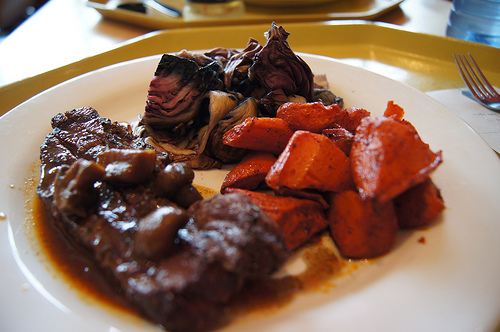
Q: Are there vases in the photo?
A: No, there are no vases.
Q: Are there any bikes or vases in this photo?
A: No, there are no vases or bikes.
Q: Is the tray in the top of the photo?
A: Yes, the tray is in the top of the image.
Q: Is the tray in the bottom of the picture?
A: No, the tray is in the top of the image.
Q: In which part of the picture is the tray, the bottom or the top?
A: The tray is in the top of the image.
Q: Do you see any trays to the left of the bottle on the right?
A: Yes, there is a tray to the left of the bottle.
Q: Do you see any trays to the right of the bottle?
A: No, the tray is to the left of the bottle.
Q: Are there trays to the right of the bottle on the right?
A: No, the tray is to the left of the bottle.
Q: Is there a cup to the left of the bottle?
A: No, there is a tray to the left of the bottle.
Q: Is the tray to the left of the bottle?
A: Yes, the tray is to the left of the bottle.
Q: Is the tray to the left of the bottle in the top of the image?
A: Yes, the tray is to the left of the bottle.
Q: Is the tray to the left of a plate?
A: No, the tray is to the left of the bottle.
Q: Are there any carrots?
A: Yes, there is a carrot.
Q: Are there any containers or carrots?
A: Yes, there is a carrot.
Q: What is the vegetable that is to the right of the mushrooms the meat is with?
A: The vegetable is a carrot.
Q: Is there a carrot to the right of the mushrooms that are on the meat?
A: Yes, there is a carrot to the right of the mushrooms.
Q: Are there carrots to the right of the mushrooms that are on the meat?
A: Yes, there is a carrot to the right of the mushrooms.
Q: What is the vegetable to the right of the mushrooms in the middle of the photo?
A: The vegetable is a carrot.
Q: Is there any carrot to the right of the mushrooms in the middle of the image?
A: Yes, there is a carrot to the right of the mushrooms.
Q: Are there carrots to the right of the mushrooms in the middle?
A: Yes, there is a carrot to the right of the mushrooms.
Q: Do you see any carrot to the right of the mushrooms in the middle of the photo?
A: Yes, there is a carrot to the right of the mushrooms.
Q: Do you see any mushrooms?
A: Yes, there are mushrooms.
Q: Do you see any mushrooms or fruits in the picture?
A: Yes, there are mushrooms.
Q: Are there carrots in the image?
A: Yes, there are carrots.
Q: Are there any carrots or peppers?
A: Yes, there are carrots.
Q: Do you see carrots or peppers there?
A: Yes, there are carrots.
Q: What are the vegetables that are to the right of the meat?
A: The vegetables are carrots.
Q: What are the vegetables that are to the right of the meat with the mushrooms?
A: The vegetables are carrots.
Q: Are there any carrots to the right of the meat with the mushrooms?
A: Yes, there are carrots to the right of the meat.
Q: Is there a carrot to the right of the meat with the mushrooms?
A: Yes, there are carrots to the right of the meat.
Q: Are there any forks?
A: Yes, there is a fork.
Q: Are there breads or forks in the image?
A: Yes, there is a fork.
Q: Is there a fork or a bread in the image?
A: Yes, there is a fork.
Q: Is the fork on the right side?
A: Yes, the fork is on the right of the image.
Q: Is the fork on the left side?
A: No, the fork is on the right of the image.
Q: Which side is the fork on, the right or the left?
A: The fork is on the right of the image.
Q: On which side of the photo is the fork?
A: The fork is on the right of the image.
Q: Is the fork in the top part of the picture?
A: Yes, the fork is in the top of the image.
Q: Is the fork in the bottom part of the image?
A: No, the fork is in the top of the image.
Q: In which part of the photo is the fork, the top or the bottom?
A: The fork is in the top of the image.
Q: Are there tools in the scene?
A: No, there are no tools.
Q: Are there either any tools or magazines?
A: No, there are no tools or magazines.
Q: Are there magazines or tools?
A: No, there are no tools or magazines.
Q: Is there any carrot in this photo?
A: Yes, there is a carrot.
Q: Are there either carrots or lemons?
A: Yes, there is a carrot.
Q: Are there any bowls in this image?
A: No, there are no bowls.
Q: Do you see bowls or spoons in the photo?
A: No, there are no bowls or spoons.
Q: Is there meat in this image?
A: Yes, there is meat.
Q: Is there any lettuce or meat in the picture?
A: Yes, there is meat.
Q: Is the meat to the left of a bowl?
A: No, the meat is to the left of a carrot.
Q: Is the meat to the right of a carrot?
A: No, the meat is to the left of a carrot.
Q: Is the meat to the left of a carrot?
A: Yes, the meat is to the left of a carrot.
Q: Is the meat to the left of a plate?
A: No, the meat is to the left of a carrot.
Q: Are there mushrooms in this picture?
A: Yes, there are mushrooms.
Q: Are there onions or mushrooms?
A: Yes, there are mushrooms.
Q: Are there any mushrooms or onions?
A: Yes, there are mushrooms.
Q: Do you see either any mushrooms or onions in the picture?
A: Yes, there are mushrooms.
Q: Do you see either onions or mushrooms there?
A: Yes, there are mushrooms.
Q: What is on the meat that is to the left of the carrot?
A: The mushrooms are on the meat.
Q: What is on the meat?
A: The mushrooms are on the meat.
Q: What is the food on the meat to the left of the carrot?
A: The food is mushrooms.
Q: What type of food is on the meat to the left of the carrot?
A: The food is mushrooms.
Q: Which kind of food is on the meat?
A: The food is mushrooms.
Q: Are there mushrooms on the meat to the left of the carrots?
A: Yes, there are mushrooms on the meat.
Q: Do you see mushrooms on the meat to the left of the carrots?
A: Yes, there are mushrooms on the meat.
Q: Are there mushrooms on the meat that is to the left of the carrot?
A: Yes, there are mushrooms on the meat.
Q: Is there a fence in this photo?
A: Yes, there is a fence.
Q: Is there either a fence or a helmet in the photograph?
A: Yes, there is a fence.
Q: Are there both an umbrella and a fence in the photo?
A: No, there is a fence but no umbrellas.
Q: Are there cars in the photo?
A: No, there are no cars.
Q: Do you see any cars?
A: No, there are no cars.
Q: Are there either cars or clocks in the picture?
A: No, there are no cars or clocks.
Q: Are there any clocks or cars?
A: No, there are no cars or clocks.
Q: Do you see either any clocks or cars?
A: No, there are no cars or clocks.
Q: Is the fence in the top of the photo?
A: Yes, the fence is in the top of the image.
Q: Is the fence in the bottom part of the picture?
A: No, the fence is in the top of the image.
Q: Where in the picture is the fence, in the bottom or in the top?
A: The fence is in the top of the image.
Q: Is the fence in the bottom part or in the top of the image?
A: The fence is in the top of the image.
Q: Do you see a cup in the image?
A: No, there are no cups.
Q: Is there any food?
A: Yes, there is food.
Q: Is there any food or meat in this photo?
A: Yes, there is food.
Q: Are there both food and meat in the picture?
A: Yes, there are both food and meat.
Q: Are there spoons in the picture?
A: No, there are no spoons.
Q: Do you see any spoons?
A: No, there are no spoons.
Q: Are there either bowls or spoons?
A: No, there are no spoons or bowls.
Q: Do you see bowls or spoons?
A: No, there are no spoons or bowls.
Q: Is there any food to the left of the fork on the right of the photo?
A: Yes, there is food to the left of the fork.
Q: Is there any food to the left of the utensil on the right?
A: Yes, there is food to the left of the fork.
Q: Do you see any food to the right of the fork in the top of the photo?
A: No, the food is to the left of the fork.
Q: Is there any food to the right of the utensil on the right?
A: No, the food is to the left of the fork.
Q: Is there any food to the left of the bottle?
A: Yes, there is food to the left of the bottle.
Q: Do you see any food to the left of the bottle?
A: Yes, there is food to the left of the bottle.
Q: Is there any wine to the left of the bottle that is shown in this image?
A: No, there is food to the left of the bottle.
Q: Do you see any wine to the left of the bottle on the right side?
A: No, there is food to the left of the bottle.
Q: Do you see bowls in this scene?
A: No, there are no bowls.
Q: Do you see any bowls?
A: No, there are no bowls.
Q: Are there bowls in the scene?
A: No, there are no bowls.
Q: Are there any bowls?
A: No, there are no bowls.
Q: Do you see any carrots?
A: Yes, there is a carrot.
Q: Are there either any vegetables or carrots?
A: Yes, there is a carrot.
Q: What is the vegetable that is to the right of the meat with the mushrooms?
A: The vegetable is a carrot.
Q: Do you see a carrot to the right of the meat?
A: Yes, there is a carrot to the right of the meat.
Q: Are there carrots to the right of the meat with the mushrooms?
A: Yes, there is a carrot to the right of the meat.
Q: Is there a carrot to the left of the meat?
A: No, the carrot is to the right of the meat.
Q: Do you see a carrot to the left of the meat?
A: No, the carrot is to the right of the meat.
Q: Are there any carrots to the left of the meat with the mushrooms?
A: No, the carrot is to the right of the meat.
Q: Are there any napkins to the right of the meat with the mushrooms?
A: No, there is a carrot to the right of the meat.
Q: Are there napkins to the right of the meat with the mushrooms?
A: No, there is a carrot to the right of the meat.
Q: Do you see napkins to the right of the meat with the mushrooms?
A: No, there is a carrot to the right of the meat.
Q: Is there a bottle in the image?
A: Yes, there is a bottle.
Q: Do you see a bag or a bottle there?
A: Yes, there is a bottle.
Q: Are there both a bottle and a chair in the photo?
A: No, there is a bottle but no chairs.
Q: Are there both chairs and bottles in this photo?
A: No, there is a bottle but no chairs.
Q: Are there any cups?
A: No, there are no cups.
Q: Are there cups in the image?
A: No, there are no cups.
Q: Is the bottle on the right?
A: Yes, the bottle is on the right of the image.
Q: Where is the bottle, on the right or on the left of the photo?
A: The bottle is on the right of the image.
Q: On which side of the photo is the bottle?
A: The bottle is on the right of the image.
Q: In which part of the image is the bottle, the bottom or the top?
A: The bottle is in the top of the image.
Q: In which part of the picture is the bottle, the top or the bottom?
A: The bottle is in the top of the image.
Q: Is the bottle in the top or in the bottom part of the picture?
A: The bottle is in the top of the image.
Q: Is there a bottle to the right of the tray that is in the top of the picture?
A: Yes, there is a bottle to the right of the tray.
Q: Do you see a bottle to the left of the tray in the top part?
A: No, the bottle is to the right of the tray.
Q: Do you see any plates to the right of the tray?
A: No, there is a bottle to the right of the tray.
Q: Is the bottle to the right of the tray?
A: Yes, the bottle is to the right of the tray.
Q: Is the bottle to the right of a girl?
A: No, the bottle is to the right of the tray.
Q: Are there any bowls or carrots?
A: Yes, there is a carrot.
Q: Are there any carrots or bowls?
A: Yes, there is a carrot.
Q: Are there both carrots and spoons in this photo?
A: No, there is a carrot but no spoons.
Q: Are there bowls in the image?
A: No, there are no bowls.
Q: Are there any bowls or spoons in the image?
A: No, there are no bowls or spoons.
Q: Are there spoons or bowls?
A: No, there are no bowls or spoons.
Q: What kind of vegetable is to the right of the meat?
A: The vegetable is a carrot.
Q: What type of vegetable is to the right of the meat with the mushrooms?
A: The vegetable is a carrot.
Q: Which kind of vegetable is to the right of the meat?
A: The vegetable is a carrot.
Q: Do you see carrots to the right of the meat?
A: Yes, there is a carrot to the right of the meat.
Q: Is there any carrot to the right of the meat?
A: Yes, there is a carrot to the right of the meat.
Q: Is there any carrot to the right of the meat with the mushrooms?
A: Yes, there is a carrot to the right of the meat.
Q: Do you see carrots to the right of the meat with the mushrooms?
A: Yes, there is a carrot to the right of the meat.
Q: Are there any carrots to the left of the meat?
A: No, the carrot is to the right of the meat.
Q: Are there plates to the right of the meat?
A: No, there is a carrot to the right of the meat.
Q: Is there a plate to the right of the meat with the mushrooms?
A: No, there is a carrot to the right of the meat.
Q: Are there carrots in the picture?
A: Yes, there is a carrot.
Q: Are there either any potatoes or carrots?
A: Yes, there is a carrot.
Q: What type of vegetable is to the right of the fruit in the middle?
A: The vegetable is a carrot.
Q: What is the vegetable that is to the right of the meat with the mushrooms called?
A: The vegetable is a carrot.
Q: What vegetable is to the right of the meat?
A: The vegetable is a carrot.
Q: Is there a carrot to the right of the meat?
A: Yes, there is a carrot to the right of the meat.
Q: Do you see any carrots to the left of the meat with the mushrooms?
A: No, the carrot is to the right of the meat.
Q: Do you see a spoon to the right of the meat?
A: No, there is a carrot to the right of the meat.